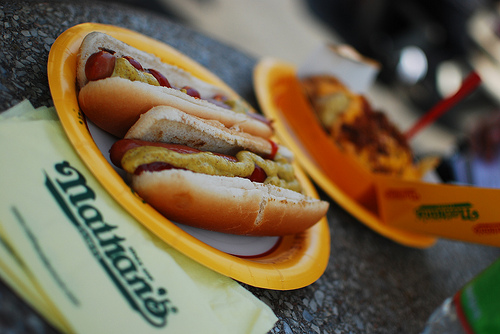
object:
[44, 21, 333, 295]
plate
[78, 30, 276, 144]
bun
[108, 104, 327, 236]
bun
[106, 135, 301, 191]
frank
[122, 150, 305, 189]
mustard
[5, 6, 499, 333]
table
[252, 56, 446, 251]
plate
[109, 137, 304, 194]
hot dog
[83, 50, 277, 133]
hot dog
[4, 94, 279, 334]
napkin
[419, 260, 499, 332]
bottle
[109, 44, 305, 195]
condiments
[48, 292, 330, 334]
plate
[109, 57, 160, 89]
mustard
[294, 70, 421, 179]
food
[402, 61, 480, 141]
fork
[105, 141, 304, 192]
ketchup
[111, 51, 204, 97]
ketchup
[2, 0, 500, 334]
counter top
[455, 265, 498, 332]
label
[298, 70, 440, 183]
fries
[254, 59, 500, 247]
box